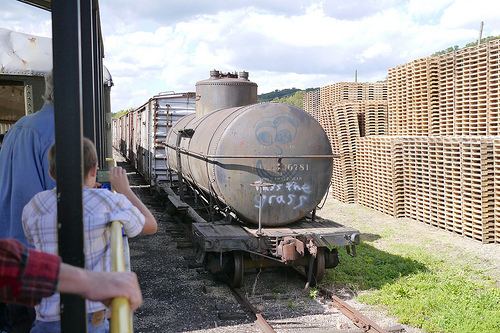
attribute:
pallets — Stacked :
[302, 35, 497, 245]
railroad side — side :
[363, 244, 498, 291]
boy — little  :
[20, 136, 157, 330]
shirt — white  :
[20, 185, 145, 322]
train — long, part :
[109, 63, 373, 291]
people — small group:
[4, 48, 170, 331]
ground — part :
[112, 153, 498, 329]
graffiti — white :
[254, 166, 312, 226]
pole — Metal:
[56, 0, 88, 330]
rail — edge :
[106, 151, 131, 329]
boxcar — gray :
[134, 92, 201, 184]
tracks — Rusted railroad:
[228, 285, 365, 332]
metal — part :
[198, 105, 370, 241]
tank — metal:
[146, 44, 356, 274]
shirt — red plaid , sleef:
[12, 241, 69, 305]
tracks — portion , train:
[215, 274, 406, 331]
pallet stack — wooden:
[401, 140, 490, 240]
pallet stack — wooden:
[436, 40, 499, 132]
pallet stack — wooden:
[381, 59, 433, 127]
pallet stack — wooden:
[356, 130, 402, 217]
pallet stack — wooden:
[321, 96, 364, 198]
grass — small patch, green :
[390, 246, 466, 315]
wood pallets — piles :
[358, 31, 497, 240]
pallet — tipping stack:
[318, 102, 360, 139]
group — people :
[2, 65, 143, 332]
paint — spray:
[247, 174, 318, 218]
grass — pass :
[354, 247, 483, 325]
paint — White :
[246, 180, 319, 224]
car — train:
[158, 63, 360, 257]